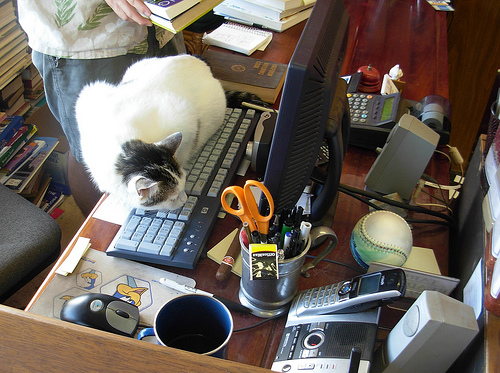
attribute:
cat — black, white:
[75, 53, 228, 212]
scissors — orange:
[219, 179, 277, 243]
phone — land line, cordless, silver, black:
[270, 268, 407, 372]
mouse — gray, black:
[60, 293, 142, 337]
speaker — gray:
[366, 113, 440, 199]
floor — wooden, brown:
[2, 192, 90, 311]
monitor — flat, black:
[263, 0, 350, 229]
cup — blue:
[138, 293, 235, 360]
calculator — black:
[346, 92, 454, 148]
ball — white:
[350, 210, 413, 272]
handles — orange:
[221, 178, 276, 233]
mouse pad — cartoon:
[28, 244, 198, 344]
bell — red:
[356, 64, 383, 91]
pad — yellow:
[207, 224, 246, 276]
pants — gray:
[32, 49, 147, 161]